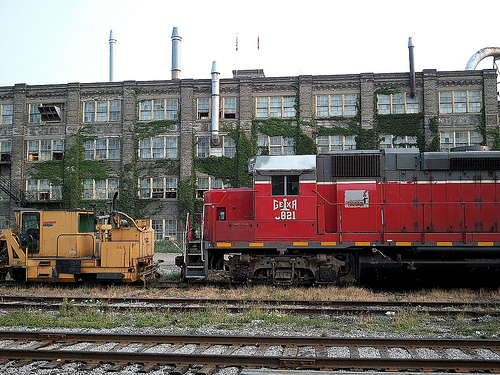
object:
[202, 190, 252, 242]
engine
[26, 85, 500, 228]
green ivy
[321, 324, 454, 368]
ground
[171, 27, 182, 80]
stack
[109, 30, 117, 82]
stack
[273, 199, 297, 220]
logo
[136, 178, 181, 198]
windows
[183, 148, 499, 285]
train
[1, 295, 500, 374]
tracks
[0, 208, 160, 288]
machinery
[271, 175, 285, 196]
window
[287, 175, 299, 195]
window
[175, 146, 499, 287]
red train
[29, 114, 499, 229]
kudzu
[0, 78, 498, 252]
wall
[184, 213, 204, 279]
stairs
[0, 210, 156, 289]
train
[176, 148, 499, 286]
car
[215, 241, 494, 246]
line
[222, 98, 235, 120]
window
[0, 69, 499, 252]
building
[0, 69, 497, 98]
cornice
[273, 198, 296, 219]
lettering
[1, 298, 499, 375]
gravel